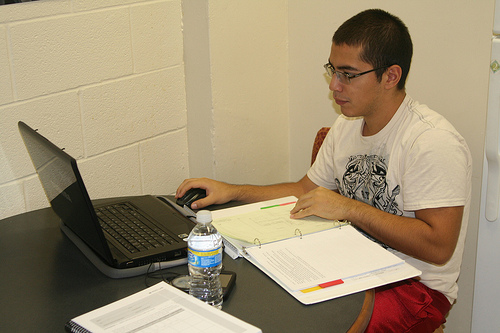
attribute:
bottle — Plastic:
[184, 206, 225, 308]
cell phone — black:
[159, 263, 277, 324]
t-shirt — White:
[308, 99, 475, 310]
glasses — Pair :
[319, 63, 379, 84]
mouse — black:
[176, 186, 203, 205]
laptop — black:
[19, 124, 209, 266]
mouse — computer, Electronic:
[171, 187, 206, 207]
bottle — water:
[189, 206, 224, 303]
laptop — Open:
[13, 113, 207, 295]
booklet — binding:
[68, 277, 265, 331]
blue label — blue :
[185, 246, 223, 266]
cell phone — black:
[200, 270, 236, 284]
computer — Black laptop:
[15, 120, 232, 299]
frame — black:
[357, 66, 375, 80]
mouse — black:
[176, 182, 211, 206]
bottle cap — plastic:
[194, 206, 213, 226]